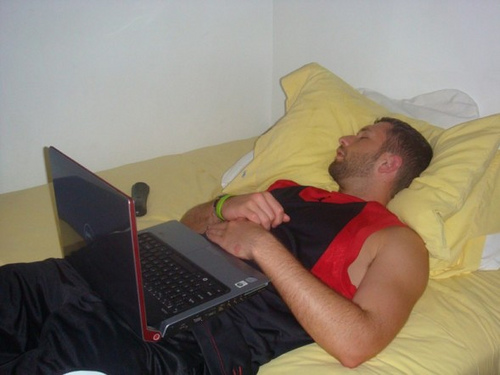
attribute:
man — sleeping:
[0, 118, 433, 374]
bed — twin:
[0, 135, 499, 374]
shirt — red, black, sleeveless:
[183, 180, 410, 374]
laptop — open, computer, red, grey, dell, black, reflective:
[44, 145, 271, 343]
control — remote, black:
[133, 184, 147, 216]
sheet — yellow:
[0, 137, 499, 373]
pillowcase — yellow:
[222, 63, 499, 278]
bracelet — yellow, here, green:
[214, 192, 234, 221]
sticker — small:
[235, 275, 256, 288]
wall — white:
[1, 2, 274, 194]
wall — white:
[276, 0, 498, 122]